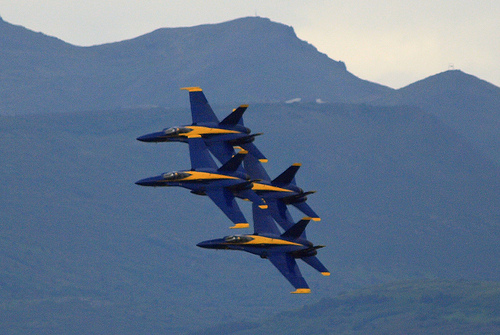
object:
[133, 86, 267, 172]
planes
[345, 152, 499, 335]
air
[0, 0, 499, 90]
clouds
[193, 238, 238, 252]
front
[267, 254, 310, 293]
wing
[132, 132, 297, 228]
planes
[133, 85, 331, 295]
formation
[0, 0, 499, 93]
sky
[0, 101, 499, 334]
mountain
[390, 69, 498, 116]
hill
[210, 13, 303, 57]
top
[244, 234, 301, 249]
strip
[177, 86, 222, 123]
wing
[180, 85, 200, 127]
edge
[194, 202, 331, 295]
airplane